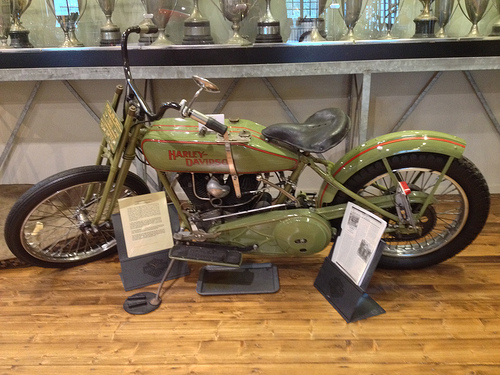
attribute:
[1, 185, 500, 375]
floor — portion, wooden, light brown, hardwood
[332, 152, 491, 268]
wheel — rare, back wheel, chrome, black, rubber, metal, grey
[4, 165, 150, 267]
wheel — rare, front wheel, steering wheel, chrome, black, rubber, metal, grey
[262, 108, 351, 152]
seat — portion, leather, black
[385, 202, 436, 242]
gear — portion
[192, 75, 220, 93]
mirror — side mirror, silver, rear view mirror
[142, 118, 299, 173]
tank — portion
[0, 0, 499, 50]
trophies — portion, many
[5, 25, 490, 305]
motorcycle — green, antique, harley davidson, red, vintage, on display, olive green, restored, green red, black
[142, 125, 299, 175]
stripe — red, orange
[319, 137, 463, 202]
stripe — red, orange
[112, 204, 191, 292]
document holder — black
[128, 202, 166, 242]
words — typed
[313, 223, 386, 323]
document holder — black, metal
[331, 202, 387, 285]
paper — photocopied, white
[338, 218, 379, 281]
words — typed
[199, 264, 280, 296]
tray — black, silver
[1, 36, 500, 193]
table — metal, long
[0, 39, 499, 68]
stripe — black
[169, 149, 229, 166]
words — harley davidson, red paint, red, decal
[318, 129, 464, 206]
fender — back fender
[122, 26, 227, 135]
handle bars — black, grey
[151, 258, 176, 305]
kickstand — metal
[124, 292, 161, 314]
mat — black, rubber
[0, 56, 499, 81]
bar — grey, metal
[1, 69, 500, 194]
wall — tan